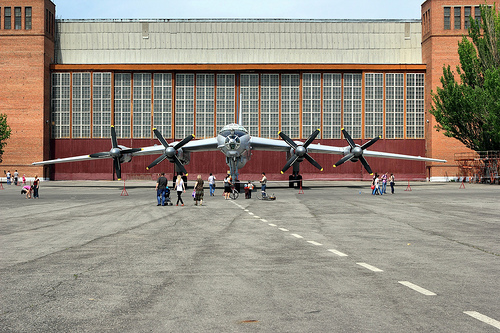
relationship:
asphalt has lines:
[2, 182, 497, 328] [135, 194, 257, 316]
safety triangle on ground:
[401, 179, 412, 190] [2, 176, 494, 332]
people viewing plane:
[0, 160, 473, 207] [48, 114, 462, 196]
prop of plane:
[332, 127, 381, 176] [23, 117, 460, 204]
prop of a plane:
[336, 122, 389, 182] [38, 115, 459, 212]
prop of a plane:
[87, 125, 141, 181] [31, 121, 447, 188]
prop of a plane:
[145, 127, 196, 176] [31, 121, 447, 188]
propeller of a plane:
[275, 125, 324, 174] [31, 121, 447, 188]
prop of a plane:
[332, 127, 381, 176] [31, 121, 447, 188]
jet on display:
[22, 118, 462, 212] [28, 119, 451, 189]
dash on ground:
[0, 177, 500, 298] [2, 176, 500, 333]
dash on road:
[289, 227, 425, 242] [5, 185, 496, 325]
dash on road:
[0, 177, 500, 298] [132, 193, 470, 323]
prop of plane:
[28, 120, 450, 199] [23, 101, 473, 208]